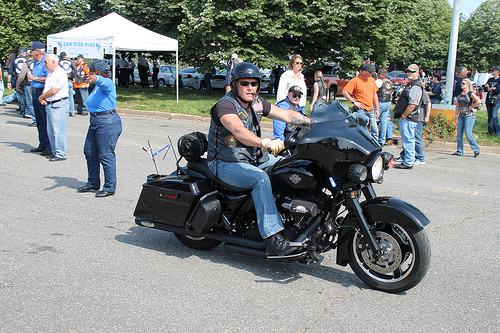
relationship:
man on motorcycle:
[206, 62, 319, 259] [131, 98, 433, 293]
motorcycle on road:
[131, 98, 433, 293] [5, 102, 498, 331]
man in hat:
[341, 64, 381, 142] [15, 33, 53, 58]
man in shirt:
[341, 64, 381, 142] [350, 73, 378, 113]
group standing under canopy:
[112, 51, 164, 91] [46, 7, 181, 99]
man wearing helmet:
[206, 62, 317, 259] [229, 61, 265, 84]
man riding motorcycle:
[206, 62, 317, 259] [129, 120, 439, 314]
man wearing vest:
[206, 62, 317, 259] [206, 95, 265, 160]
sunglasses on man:
[236, 78, 265, 88] [196, 55, 306, 265]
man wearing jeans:
[206, 62, 319, 259] [208, 150, 286, 240]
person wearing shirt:
[78, 57, 123, 197] [86, 75, 118, 112]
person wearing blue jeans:
[78, 57, 123, 197] [80, 112, 121, 189]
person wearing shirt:
[389, 58, 449, 174] [278, 72, 309, 105]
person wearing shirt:
[74, 59, 122, 198] [80, 75, 119, 126]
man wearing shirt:
[339, 60, 383, 150] [340, 67, 382, 112]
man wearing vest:
[206, 62, 317, 259] [209, 96, 273, 163]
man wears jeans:
[206, 62, 317, 259] [204, 152, 314, 238]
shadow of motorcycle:
[113, 224, 405, 294] [131, 98, 433, 293]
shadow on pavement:
[113, 224, 405, 294] [0, 103, 498, 331]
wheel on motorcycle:
[348, 216, 426, 295] [129, 140, 431, 292]